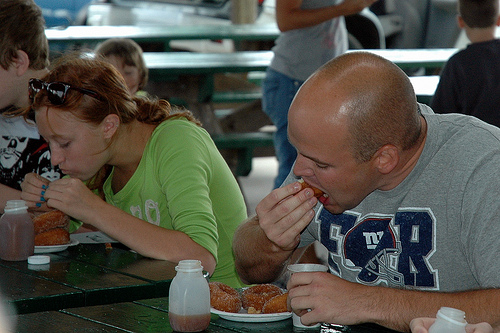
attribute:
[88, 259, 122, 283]
table — green, black, wooden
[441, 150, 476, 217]
tee shirt — grey, green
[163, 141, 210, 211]
shirt — green, gray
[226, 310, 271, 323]
plate — white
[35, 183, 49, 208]
finger nails — blue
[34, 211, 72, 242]
doughnuts — small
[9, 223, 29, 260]
bottle — plastic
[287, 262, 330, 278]
cup — white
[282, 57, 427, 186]
head — bald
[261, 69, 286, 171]
jeans — blue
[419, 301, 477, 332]
container — plastic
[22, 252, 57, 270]
cap — white